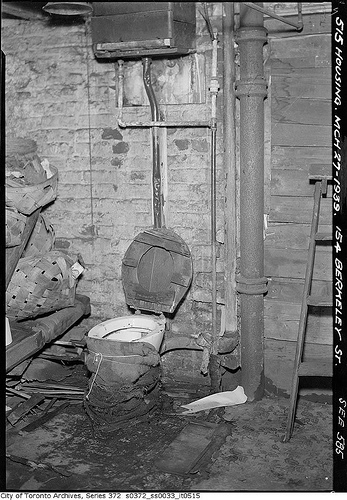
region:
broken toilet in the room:
[70, 199, 212, 444]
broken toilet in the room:
[75, 221, 201, 428]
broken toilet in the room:
[76, 217, 195, 401]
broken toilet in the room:
[75, 215, 190, 409]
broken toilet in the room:
[73, 209, 212, 424]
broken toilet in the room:
[84, 208, 214, 410]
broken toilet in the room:
[77, 210, 213, 418]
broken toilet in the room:
[73, 208, 207, 402]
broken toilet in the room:
[78, 219, 215, 429]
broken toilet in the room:
[76, 211, 215, 432]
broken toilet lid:
[114, 221, 197, 318]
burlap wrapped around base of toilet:
[76, 334, 169, 440]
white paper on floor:
[179, 378, 251, 421]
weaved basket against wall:
[7, 239, 82, 324]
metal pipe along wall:
[230, 1, 275, 403]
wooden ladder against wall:
[279, 160, 334, 452]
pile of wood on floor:
[0, 318, 89, 419]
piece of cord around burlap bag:
[82, 345, 147, 370]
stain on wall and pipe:
[249, 367, 333, 409]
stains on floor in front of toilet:
[48, 410, 184, 487]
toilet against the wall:
[86, 222, 198, 419]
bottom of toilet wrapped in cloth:
[77, 329, 178, 428]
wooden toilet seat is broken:
[118, 225, 200, 318]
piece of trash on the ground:
[174, 376, 258, 427]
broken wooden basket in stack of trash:
[7, 244, 89, 330]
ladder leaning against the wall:
[279, 159, 341, 447]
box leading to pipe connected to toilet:
[82, 5, 204, 231]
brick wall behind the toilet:
[22, 50, 264, 278]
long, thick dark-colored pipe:
[213, 11, 283, 405]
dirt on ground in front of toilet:
[49, 409, 212, 477]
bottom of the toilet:
[82, 382, 152, 430]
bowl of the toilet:
[114, 328, 144, 345]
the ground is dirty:
[74, 432, 171, 477]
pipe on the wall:
[233, 252, 269, 403]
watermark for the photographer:
[5, 482, 25, 496]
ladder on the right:
[273, 311, 328, 440]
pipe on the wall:
[148, 92, 179, 227]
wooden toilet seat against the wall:
[120, 222, 193, 314]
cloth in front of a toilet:
[74, 326, 171, 429]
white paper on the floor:
[177, 375, 266, 422]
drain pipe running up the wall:
[228, 38, 269, 404]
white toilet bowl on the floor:
[87, 302, 175, 382]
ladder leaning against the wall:
[283, 154, 340, 455]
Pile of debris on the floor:
[5, 125, 83, 426]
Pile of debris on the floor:
[5, 223, 93, 388]